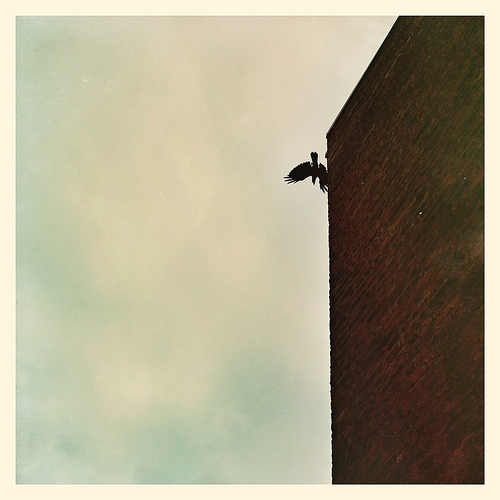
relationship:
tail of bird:
[311, 175, 321, 185] [283, 150, 335, 196]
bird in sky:
[283, 150, 335, 196] [15, 26, 306, 498]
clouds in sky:
[41, 49, 234, 408] [15, 26, 306, 498]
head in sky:
[301, 148, 324, 159] [19, 10, 326, 318]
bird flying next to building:
[283, 150, 335, 196] [323, 27, 480, 404]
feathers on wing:
[283, 173, 303, 184] [283, 157, 318, 187]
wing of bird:
[283, 157, 318, 187] [277, 146, 334, 200]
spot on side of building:
[414, 203, 423, 222] [325, 27, 471, 419]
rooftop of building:
[305, 23, 473, 133] [319, 19, 477, 482]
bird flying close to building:
[283, 150, 335, 196] [319, 19, 477, 482]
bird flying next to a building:
[274, 134, 335, 196] [319, 19, 477, 482]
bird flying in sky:
[283, 150, 335, 196] [15, 17, 329, 430]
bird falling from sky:
[283, 150, 335, 196] [10, 17, 330, 480]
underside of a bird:
[311, 157, 317, 179] [283, 150, 335, 196]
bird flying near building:
[283, 150, 335, 196] [319, 19, 477, 482]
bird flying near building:
[283, 150, 335, 196] [325, 28, 480, 498]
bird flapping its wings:
[283, 150, 335, 196] [280, 159, 331, 199]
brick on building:
[342, 250, 423, 332] [267, 48, 480, 488]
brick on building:
[342, 204, 481, 483] [212, 53, 498, 473]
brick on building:
[342, 204, 481, 483] [315, 90, 498, 443]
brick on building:
[342, 204, 481, 483] [319, 71, 499, 431]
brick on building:
[342, 204, 481, 483] [302, 78, 476, 478]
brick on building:
[342, 204, 481, 483] [318, 93, 483, 474]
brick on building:
[342, 204, 481, 483] [318, 106, 496, 478]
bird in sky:
[283, 150, 335, 196] [83, 51, 362, 327]